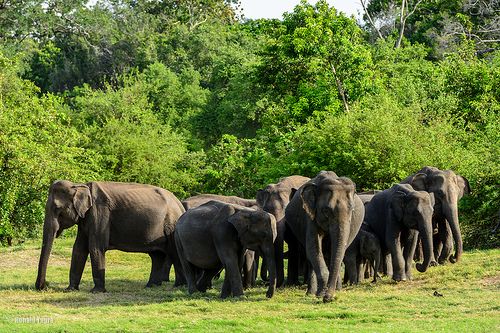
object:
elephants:
[261, 173, 311, 289]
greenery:
[0, 0, 499, 246]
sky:
[228, 0, 372, 27]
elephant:
[36, 178, 187, 293]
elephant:
[174, 200, 277, 299]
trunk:
[263, 244, 280, 298]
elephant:
[400, 166, 472, 264]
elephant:
[363, 182, 436, 283]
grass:
[1, 234, 499, 332]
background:
[0, 1, 499, 251]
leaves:
[28, 72, 43, 90]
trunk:
[34, 215, 62, 291]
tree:
[251, 1, 388, 115]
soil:
[1, 234, 500, 331]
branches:
[359, 1, 424, 49]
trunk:
[441, 200, 464, 264]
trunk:
[320, 215, 355, 303]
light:
[271, 216, 278, 242]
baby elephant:
[344, 226, 383, 285]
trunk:
[416, 219, 433, 273]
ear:
[71, 184, 94, 218]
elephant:
[182, 193, 257, 210]